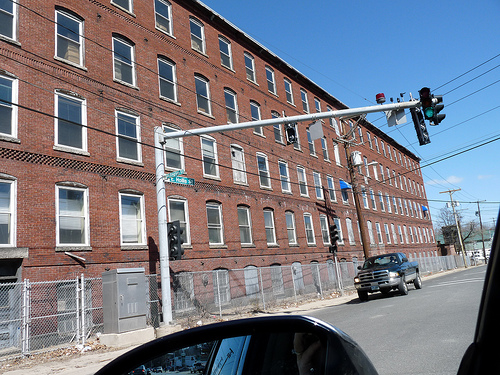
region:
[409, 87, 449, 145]
black traffic lights with a green light showing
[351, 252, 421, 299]
pick up truck parked on a city street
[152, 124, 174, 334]
gray metal pole holding a traffic light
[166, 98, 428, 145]
cross bar holding traffic lights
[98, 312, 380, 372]
black rear view mirror on a car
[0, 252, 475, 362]
chain link fence on a sidewalk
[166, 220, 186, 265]
black traffic light on a gray metal pole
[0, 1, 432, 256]
window in the side of a red brick building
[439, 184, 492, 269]
utility poles on the side of a city street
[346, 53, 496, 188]
power line wires above a city street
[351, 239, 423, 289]
the truck is black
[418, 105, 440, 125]
the green light is on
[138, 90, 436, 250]
the building is covered with windwows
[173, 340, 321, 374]
reflection is in the miror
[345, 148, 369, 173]
transformer is on the pole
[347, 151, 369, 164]
transformer is white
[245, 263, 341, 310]
the fence barricades the building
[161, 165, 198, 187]
the sign post is blue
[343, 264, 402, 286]
the lights are on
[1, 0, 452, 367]
The building is brick.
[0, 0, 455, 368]
The building is tall.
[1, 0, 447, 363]
The building is long.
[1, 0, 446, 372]
The building is fenced in.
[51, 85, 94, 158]
The window is rectangular.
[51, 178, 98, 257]
The window is rectangular.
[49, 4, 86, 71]
The window is rectangular.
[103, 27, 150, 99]
The window is rectangular.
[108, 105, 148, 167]
The window is rectangular.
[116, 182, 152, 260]
The window is rectangular.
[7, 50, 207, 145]
windows on the building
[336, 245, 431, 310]
truck on the ground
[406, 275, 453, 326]
street under the truck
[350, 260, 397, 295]
front of the truck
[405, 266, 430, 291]
back wheel of truck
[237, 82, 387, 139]
pole above the street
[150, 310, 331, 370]
mirror of a car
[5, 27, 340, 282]
brown building with many windows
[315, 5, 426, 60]
blue sky above land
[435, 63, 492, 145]
wires above the street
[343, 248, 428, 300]
truck parked on the street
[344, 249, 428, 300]
truck is next to the fence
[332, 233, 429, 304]
truck is near the building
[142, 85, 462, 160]
signal light is near the building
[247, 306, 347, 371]
person is wearing a ring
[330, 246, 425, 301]
headlights are on on the truck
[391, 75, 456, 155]
signal light is green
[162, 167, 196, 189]
street signs are green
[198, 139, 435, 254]
the building is brown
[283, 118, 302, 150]
the window to the building is opened